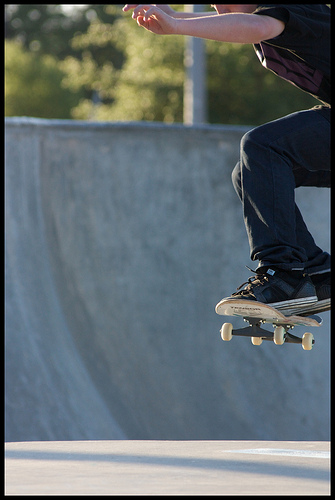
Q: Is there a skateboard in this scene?
A: Yes, there is a skateboard.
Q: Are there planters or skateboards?
A: Yes, there is a skateboard.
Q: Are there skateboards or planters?
A: Yes, there is a skateboard.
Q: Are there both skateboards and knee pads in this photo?
A: No, there is a skateboard but no knee pads.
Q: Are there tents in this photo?
A: No, there are no tents.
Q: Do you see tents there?
A: No, there are no tents.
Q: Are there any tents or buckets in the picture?
A: No, there are no tents or buckets.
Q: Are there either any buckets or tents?
A: No, there are no tents or buckets.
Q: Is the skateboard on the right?
A: Yes, the skateboard is on the right of the image.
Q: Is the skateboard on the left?
A: No, the skateboard is on the right of the image.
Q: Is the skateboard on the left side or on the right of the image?
A: The skateboard is on the right of the image.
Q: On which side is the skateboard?
A: The skateboard is on the right of the image.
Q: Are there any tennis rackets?
A: No, there are no tennis rackets.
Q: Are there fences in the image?
A: Yes, there is a fence.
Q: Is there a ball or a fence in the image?
A: Yes, there is a fence.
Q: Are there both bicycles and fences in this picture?
A: No, there is a fence but no bikes.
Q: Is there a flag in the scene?
A: No, there are no flags.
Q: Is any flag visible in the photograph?
A: No, there are no flags.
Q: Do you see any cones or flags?
A: No, there are no flags or cones.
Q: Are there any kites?
A: No, there are no kites.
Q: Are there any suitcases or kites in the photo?
A: No, there are no kites or suitcases.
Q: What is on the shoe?
A: The shoe lace is on the shoe.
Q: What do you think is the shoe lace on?
A: The shoe lace is on the shoe.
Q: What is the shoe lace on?
A: The shoe lace is on the shoe.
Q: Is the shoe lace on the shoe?
A: Yes, the shoe lace is on the shoe.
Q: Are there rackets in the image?
A: No, there are no rackets.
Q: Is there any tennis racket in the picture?
A: No, there are no rackets.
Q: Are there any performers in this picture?
A: No, there are no performers.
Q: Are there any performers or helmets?
A: No, there are no performers or helmets.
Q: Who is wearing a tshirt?
A: The boy is wearing a tshirt.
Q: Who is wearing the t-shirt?
A: The boy is wearing a tshirt.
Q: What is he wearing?
A: The boy is wearing a t-shirt.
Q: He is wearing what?
A: The boy is wearing a t-shirt.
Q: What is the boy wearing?
A: The boy is wearing a t-shirt.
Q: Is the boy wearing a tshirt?
A: Yes, the boy is wearing a tshirt.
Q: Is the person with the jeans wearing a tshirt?
A: Yes, the boy is wearing a tshirt.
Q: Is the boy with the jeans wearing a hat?
A: No, the boy is wearing a tshirt.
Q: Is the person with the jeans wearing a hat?
A: No, the boy is wearing a tshirt.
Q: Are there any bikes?
A: No, there are no bikes.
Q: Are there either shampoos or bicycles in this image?
A: No, there are no bicycles or shampoos.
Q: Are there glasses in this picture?
A: No, there are no glasses.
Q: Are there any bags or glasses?
A: No, there are no glasses or bags.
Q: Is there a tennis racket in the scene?
A: No, there are no rackets.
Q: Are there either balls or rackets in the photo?
A: No, there are no rackets or balls.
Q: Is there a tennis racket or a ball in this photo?
A: No, there are no rackets or balls.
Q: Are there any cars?
A: No, there are no cars.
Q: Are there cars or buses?
A: No, there are no cars or buses.